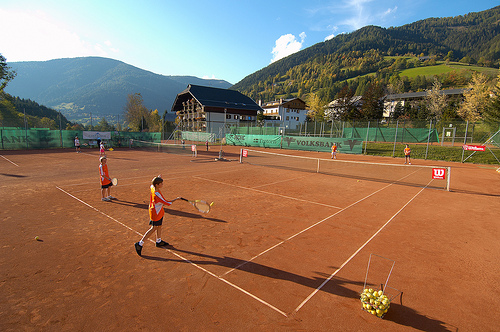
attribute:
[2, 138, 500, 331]
tennis court — clay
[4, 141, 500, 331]
clay — orange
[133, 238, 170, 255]
shoes — black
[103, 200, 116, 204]
shoes — white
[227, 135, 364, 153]
banner — green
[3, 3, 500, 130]
hills — green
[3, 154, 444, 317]
lines — white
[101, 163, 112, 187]
jersey — orange, white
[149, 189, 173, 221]
jersey — orange, white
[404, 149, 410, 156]
jersey — orange, white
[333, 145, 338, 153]
jersey — orange, white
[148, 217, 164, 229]
shorts — black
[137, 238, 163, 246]
socks — white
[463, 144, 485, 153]
sign — red, large, white